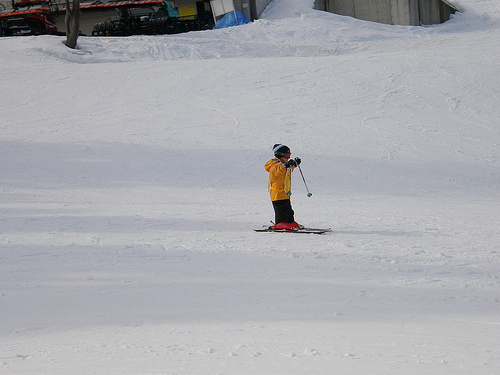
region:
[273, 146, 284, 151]
white strip on hat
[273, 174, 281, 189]
boy wearing yellow coat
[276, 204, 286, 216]
boy wearing black pants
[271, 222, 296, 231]
boy wearing red sneakers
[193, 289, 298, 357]
white snow on ground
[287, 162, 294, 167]
black gloves on hand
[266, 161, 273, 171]
yellow hood on coat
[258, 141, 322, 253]
young skier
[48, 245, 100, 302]
white snow on hill side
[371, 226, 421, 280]
white snow on hill side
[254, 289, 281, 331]
white snow on hill side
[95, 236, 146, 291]
white snow on hill side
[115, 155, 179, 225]
white snow on hill side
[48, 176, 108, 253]
white snow on hill side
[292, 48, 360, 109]
white snow on hill side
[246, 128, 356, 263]
This is a person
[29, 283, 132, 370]
section of the ice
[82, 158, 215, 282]
section of the ice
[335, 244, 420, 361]
section of the ice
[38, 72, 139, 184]
section of the ice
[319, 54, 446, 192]
section of the ice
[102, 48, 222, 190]
section of the ice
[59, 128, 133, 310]
section of the ice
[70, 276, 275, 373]
section of the ice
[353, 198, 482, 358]
section of the ice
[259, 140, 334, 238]
small child skiing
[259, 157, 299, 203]
small child wearing a bright yellow jacket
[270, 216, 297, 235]
small child wearing red ski boots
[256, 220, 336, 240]
skis are short and small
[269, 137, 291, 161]
child wearing a white and blue striped hat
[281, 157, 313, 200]
child holding a pair of ski poles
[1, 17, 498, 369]
a very flat white ski slope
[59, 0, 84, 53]
tree trunk on side of slope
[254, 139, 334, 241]
a small kid learning how to ski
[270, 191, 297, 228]
small child wearing black ski pants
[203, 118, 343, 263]
kid in the snow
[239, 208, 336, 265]
skis on the ground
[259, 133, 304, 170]
head of the kid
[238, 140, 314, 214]
kid wearing the color yellow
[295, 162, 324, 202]
ski pole in kid's hand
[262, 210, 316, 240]
red shoes on kid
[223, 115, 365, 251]
one kid in the photo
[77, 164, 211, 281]
shadow on the ground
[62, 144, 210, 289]
white snow in photo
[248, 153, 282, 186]
hood of the outfit